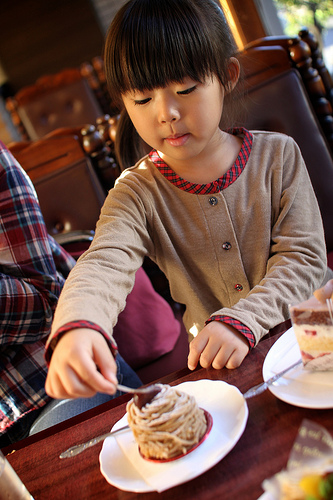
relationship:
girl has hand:
[42, 0, 327, 402] [42, 327, 118, 401]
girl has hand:
[42, 0, 327, 402] [187, 322, 249, 373]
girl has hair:
[42, 0, 327, 402] [104, 1, 238, 173]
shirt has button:
[42, 127, 328, 347] [207, 196, 218, 206]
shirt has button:
[42, 127, 328, 347] [221, 240, 233, 252]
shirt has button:
[42, 127, 328, 347] [233, 283, 243, 291]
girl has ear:
[42, 0, 327, 402] [221, 53, 239, 94]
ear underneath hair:
[221, 53, 239, 94] [104, 1, 238, 173]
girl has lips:
[42, 0, 327, 402] [162, 131, 189, 149]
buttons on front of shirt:
[208, 196, 244, 295] [42, 127, 328, 347]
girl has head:
[42, 0, 327, 402] [105, 2, 240, 159]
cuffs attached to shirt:
[42, 313, 255, 370] [42, 127, 328, 347]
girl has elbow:
[42, 0, 327, 402] [310, 255, 330, 284]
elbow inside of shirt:
[310, 255, 330, 284] [42, 127, 328, 347]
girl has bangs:
[42, 0, 327, 402] [104, 2, 213, 96]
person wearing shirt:
[1, 141, 144, 449] [1, 142, 77, 434]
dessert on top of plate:
[289, 287, 331, 375] [261, 325, 332, 410]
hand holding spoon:
[42, 327, 118, 401] [116, 384, 160, 410]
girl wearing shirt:
[42, 0, 327, 402] [42, 127, 328, 347]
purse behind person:
[69, 248, 181, 368] [1, 141, 144, 449]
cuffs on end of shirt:
[42, 313, 255, 370] [42, 127, 328, 347]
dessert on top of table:
[289, 287, 331, 375] [8, 328, 332, 500]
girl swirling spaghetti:
[42, 0, 327, 402] [125, 380, 207, 460]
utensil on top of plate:
[58, 421, 129, 461] [98, 377, 248, 493]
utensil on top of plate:
[245, 359, 301, 399] [261, 325, 332, 410]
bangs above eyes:
[104, 2, 213, 96] [133, 84, 198, 105]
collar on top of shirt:
[148, 125, 253, 193] [42, 127, 328, 347]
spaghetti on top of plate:
[125, 380, 207, 460] [98, 377, 248, 493]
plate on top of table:
[98, 377, 248, 493] [8, 328, 332, 500]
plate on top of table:
[261, 325, 332, 410] [8, 328, 332, 500]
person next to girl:
[1, 141, 144, 449] [42, 0, 327, 402]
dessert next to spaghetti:
[289, 287, 331, 375] [125, 380, 207, 460]